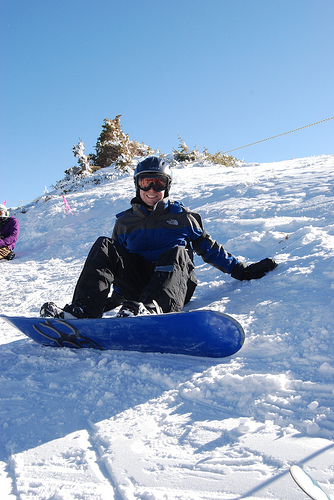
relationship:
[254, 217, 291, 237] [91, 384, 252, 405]
snow on top of ground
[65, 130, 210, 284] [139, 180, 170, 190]
man wearing goggles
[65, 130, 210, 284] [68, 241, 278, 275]
man wearing gloves